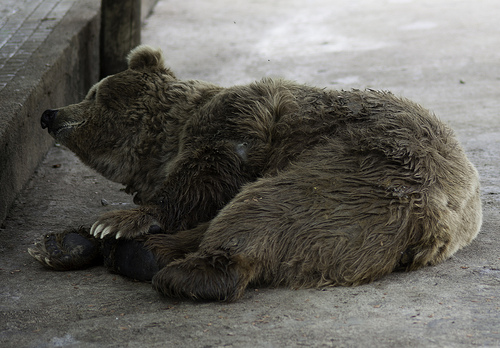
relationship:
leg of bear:
[152, 169, 395, 304] [28, 44, 486, 305]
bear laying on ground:
[28, 44, 486, 305] [0, 0, 498, 346]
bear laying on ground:
[28, 44, 486, 305] [55, 0, 498, 341]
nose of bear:
[38, 106, 58, 131] [28, 44, 486, 305]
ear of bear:
[118, 42, 168, 77] [71, 21, 432, 308]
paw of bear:
[84, 197, 184, 247] [28, 44, 486, 305]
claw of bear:
[93, 220, 104, 237] [28, 44, 486, 305]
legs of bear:
[138, 147, 259, 231] [28, 44, 486, 305]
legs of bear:
[25, 221, 123, 271] [28, 44, 486, 305]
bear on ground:
[28, 44, 486, 305] [0, 0, 498, 346]